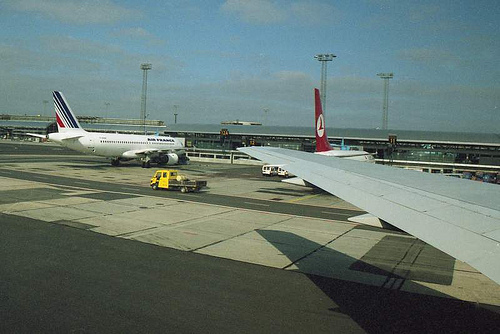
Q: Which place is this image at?
A: It is at the airport.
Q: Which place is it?
A: It is an airport.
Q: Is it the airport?
A: Yes, it is the airport.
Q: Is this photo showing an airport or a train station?
A: It is showing an airport.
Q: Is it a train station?
A: No, it is an airport.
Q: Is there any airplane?
A: Yes, there is an airplane.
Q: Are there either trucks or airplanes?
A: Yes, there is an airplane.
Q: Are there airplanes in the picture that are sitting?
A: Yes, there is an airplane that is sitting.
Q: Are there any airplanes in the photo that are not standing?
A: Yes, there is an airplane that is sitting.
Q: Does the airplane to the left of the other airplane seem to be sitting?
A: Yes, the plane is sitting.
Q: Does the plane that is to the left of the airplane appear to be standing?
A: No, the airplane is sitting.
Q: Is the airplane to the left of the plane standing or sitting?
A: The airplane is sitting.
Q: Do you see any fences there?
A: No, there are no fences.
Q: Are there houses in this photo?
A: No, there are no houses.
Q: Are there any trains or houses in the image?
A: No, there are no houses or trains.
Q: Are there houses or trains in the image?
A: No, there are no houses or trains.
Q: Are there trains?
A: No, there are no trains.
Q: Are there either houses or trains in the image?
A: No, there are no trains or houses.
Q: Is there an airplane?
A: Yes, there is an airplane.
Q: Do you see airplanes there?
A: Yes, there is an airplane.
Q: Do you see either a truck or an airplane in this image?
A: Yes, there is an airplane.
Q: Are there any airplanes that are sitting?
A: Yes, there is an airplane that is sitting.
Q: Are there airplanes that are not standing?
A: Yes, there is an airplane that is sitting.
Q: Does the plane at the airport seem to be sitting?
A: Yes, the plane is sitting.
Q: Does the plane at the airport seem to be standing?
A: No, the airplane is sitting.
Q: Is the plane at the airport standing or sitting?
A: The airplane is sitting.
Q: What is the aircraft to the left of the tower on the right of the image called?
A: The aircraft is an airplane.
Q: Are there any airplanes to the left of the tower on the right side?
A: Yes, there is an airplane to the left of the tower.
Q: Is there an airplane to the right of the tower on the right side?
A: No, the airplane is to the left of the tower.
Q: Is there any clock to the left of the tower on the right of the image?
A: No, there is an airplane to the left of the tower.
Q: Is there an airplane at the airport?
A: Yes, there is an airplane at the airport.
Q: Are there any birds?
A: No, there are no birds.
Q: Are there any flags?
A: No, there are no flags.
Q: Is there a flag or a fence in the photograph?
A: No, there are no flags or fences.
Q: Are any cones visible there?
A: No, there are no cones.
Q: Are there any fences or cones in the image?
A: No, there are no cones or fences.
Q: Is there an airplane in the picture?
A: Yes, there is an airplane.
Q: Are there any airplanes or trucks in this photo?
A: Yes, there is an airplane.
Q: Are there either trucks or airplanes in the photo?
A: Yes, there is an airplane.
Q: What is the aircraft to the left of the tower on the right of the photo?
A: The aircraft is an airplane.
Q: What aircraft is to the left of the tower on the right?
A: The aircraft is an airplane.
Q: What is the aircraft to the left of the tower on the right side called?
A: The aircraft is an airplane.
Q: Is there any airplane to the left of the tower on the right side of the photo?
A: Yes, there is an airplane to the left of the tower.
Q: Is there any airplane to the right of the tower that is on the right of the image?
A: No, the airplane is to the left of the tower.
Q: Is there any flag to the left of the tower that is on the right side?
A: No, there is an airplane to the left of the tower.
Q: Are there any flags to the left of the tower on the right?
A: No, there is an airplane to the left of the tower.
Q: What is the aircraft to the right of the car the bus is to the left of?
A: The aircraft is an airplane.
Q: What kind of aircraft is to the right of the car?
A: The aircraft is an airplane.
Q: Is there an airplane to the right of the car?
A: Yes, there is an airplane to the right of the car.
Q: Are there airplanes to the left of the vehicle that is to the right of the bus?
A: No, the airplane is to the right of the car.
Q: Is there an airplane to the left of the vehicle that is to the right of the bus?
A: No, the airplane is to the right of the car.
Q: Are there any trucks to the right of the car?
A: No, there is an airplane to the right of the car.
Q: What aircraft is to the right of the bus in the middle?
A: The aircraft is an airplane.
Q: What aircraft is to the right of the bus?
A: The aircraft is an airplane.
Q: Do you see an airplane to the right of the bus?
A: Yes, there is an airplane to the right of the bus.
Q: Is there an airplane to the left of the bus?
A: No, the airplane is to the right of the bus.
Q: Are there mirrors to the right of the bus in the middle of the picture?
A: No, there is an airplane to the right of the bus.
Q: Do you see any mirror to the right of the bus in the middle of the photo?
A: No, there is an airplane to the right of the bus.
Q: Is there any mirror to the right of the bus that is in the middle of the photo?
A: No, there is an airplane to the right of the bus.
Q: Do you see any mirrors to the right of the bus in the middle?
A: No, there is an airplane to the right of the bus.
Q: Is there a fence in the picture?
A: No, there are no fences.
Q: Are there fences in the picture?
A: No, there are no fences.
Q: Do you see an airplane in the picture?
A: Yes, there is an airplane.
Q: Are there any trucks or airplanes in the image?
A: Yes, there is an airplane.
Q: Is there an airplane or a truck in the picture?
A: Yes, there is an airplane.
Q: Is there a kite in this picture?
A: No, there are no kites.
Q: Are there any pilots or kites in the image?
A: No, there are no kites or pilots.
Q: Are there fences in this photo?
A: No, there are no fences.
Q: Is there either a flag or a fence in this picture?
A: No, there are no fences or flags.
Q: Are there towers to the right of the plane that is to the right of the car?
A: Yes, there is a tower to the right of the airplane.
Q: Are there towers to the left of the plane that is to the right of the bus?
A: No, the tower is to the right of the plane.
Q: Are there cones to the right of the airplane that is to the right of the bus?
A: No, there is a tower to the right of the airplane.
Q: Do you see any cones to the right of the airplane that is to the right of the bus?
A: No, there is a tower to the right of the airplane.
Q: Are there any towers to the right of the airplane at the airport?
A: Yes, there is a tower to the right of the airplane.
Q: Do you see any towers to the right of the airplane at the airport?
A: Yes, there is a tower to the right of the airplane.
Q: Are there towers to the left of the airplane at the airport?
A: No, the tower is to the right of the airplane.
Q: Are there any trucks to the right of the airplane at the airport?
A: No, there is a tower to the right of the airplane.